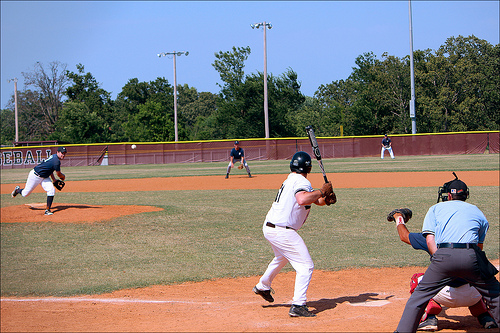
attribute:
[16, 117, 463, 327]
teams — two separate teams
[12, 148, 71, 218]
pitcher — throwing, wearing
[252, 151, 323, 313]
batter — swing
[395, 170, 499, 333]
umpire — ready, watching, behind 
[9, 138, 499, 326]
player — ready, pitching, holding, throwing, outfielders, wearing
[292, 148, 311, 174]
helmet — for protection, black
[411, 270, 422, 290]
kneepad — for protection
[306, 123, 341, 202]
bat — baseball bat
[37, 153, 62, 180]
shirt — blue, white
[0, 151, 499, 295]
grass — green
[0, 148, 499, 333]
field — grass, dirt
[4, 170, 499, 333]
sand — red, dirt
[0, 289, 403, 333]
line — white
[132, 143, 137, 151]
ball — white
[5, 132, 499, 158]
fence — red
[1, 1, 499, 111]
sky — clear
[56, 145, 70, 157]
hat — black, blue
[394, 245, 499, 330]
pant — grey